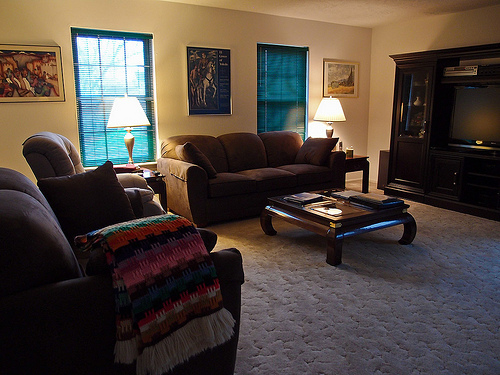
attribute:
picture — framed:
[321, 52, 372, 98]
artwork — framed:
[179, 44, 237, 122]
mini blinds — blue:
[82, 43, 138, 153]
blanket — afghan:
[2, 159, 258, 373]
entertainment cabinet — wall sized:
[366, 41, 498, 226]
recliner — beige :
[26, 126, 165, 213]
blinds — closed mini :
[265, 56, 306, 119]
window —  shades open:
[77, 42, 157, 161]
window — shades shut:
[264, 46, 309, 140]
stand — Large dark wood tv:
[362, 32, 464, 199]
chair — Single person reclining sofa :
[9, 123, 166, 215]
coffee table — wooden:
[263, 170, 428, 285]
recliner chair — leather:
[11, 110, 172, 250]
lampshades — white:
[96, 85, 366, 143]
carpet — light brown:
[306, 266, 426, 371]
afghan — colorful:
[89, 213, 248, 373]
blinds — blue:
[72, 34, 155, 170]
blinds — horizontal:
[70, 24, 155, 167]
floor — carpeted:
[193, 178, 494, 367]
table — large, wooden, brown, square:
[255, 183, 422, 273]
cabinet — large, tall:
[364, 37, 498, 229]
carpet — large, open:
[228, 212, 498, 370]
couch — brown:
[153, 125, 350, 225]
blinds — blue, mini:
[260, 47, 304, 130]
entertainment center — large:
[379, 39, 498, 221]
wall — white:
[7, 5, 368, 160]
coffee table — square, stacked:
[275, 191, 404, 275]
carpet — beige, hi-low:
[240, 210, 459, 372]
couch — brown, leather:
[186, 131, 382, 212]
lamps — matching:
[97, 76, 367, 171]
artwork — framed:
[51, 24, 352, 141]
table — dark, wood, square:
[279, 185, 415, 259]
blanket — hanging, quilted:
[77, 212, 273, 346]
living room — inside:
[25, 10, 480, 364]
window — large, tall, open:
[70, 27, 159, 168]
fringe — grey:
[110, 280, 239, 369]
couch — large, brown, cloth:
[159, 130, 358, 215]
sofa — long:
[157, 125, 367, 228]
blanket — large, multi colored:
[94, 206, 221, 316]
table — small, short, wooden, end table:
[344, 163, 384, 193]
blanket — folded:
[95, 215, 234, 370]